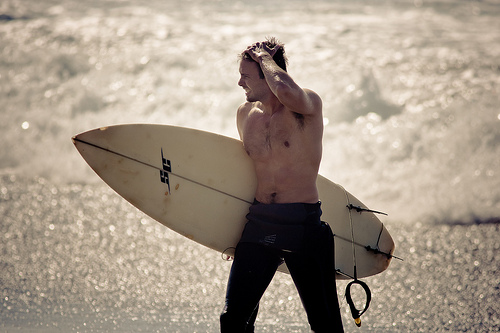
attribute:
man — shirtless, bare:
[218, 37, 346, 332]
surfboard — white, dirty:
[70, 123, 396, 281]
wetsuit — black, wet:
[221, 199, 345, 332]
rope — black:
[337, 180, 372, 326]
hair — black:
[239, 36, 289, 79]